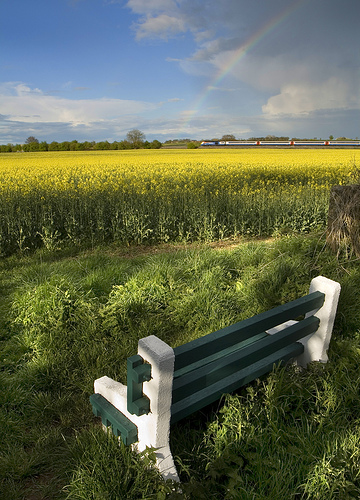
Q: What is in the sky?
A: Rainbow.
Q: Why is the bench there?
A: To sit.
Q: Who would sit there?
A: Farmers.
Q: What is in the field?
A: Flowers.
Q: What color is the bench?
A: Green.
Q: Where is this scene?
A: Open field.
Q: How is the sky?
A: Partly cloudy.